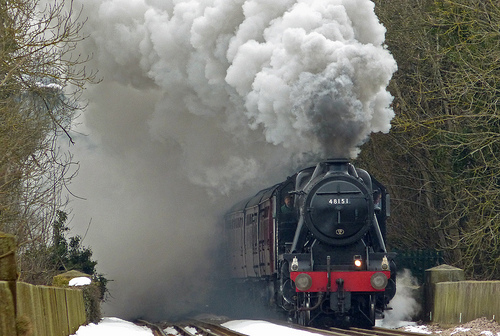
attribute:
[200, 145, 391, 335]
train — black, red, smokey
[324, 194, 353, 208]
numbers — id, engines, white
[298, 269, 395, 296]
bumper — red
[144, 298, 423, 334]
tracks — train, brown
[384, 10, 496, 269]
tress — leaves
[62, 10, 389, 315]
smoke — white, black, grey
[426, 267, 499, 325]
gate — green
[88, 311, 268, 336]
snow — light, white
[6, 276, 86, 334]
fence — green, lining, yellow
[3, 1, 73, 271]
tree — leafless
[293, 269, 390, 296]
headlight — lit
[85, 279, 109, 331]
wall — bricks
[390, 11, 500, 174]
trees — small, leafless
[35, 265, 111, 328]
barrier — short